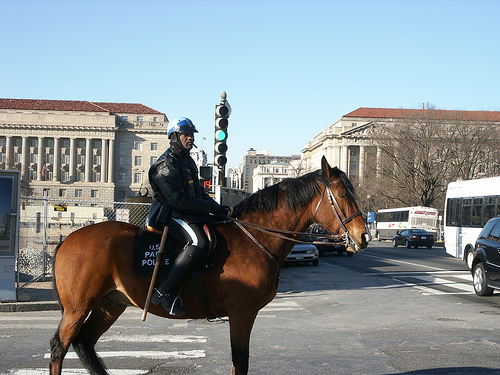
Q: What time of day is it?
A: Daytime.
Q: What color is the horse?
A: Brown.